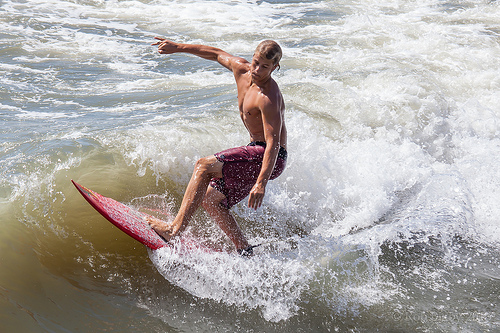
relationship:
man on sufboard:
[150, 35, 287, 257] [58, 161, 205, 261]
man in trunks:
[182, 25, 352, 240] [187, 145, 303, 224]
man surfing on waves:
[150, 35, 287, 257] [0, 91, 140, 270]